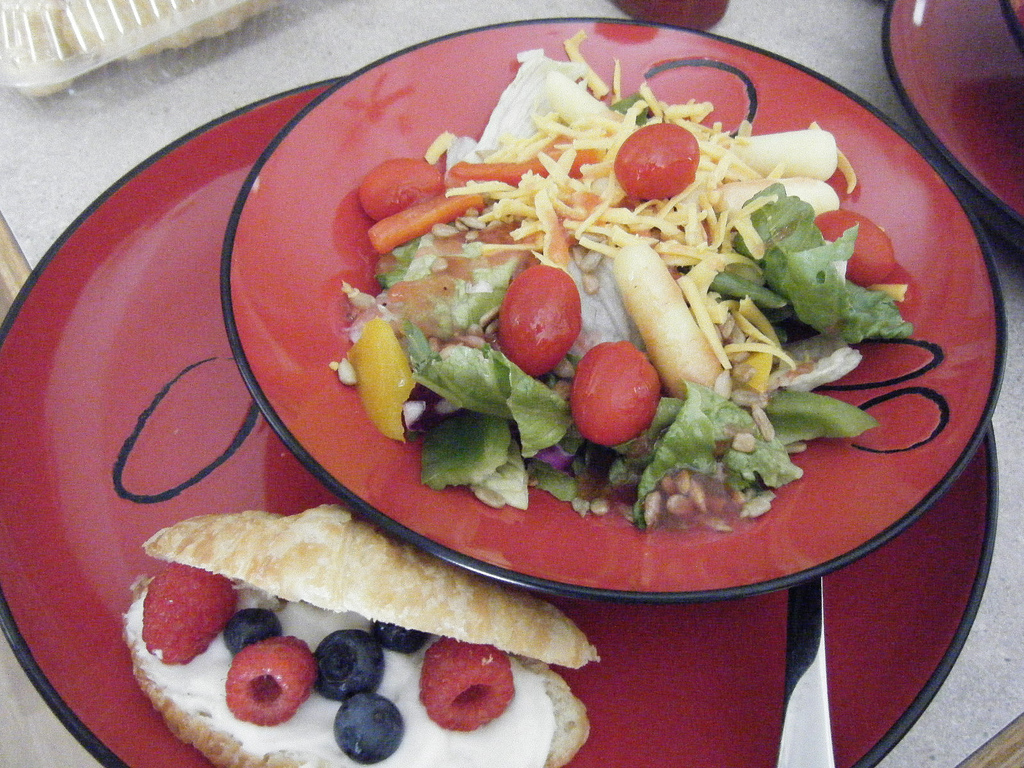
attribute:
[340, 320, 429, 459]
pepper — yellow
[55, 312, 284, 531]
design — black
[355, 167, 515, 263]
carrot — slice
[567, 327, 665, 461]
olive — red, on top 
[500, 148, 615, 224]
cheese — Shredded , on top 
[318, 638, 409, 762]
olives — on top , purple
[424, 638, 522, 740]
raspberries — red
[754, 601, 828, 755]
utensil — silver, on top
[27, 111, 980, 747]
plate — red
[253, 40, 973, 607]
bowl — sitting on top 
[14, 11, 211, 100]
container — sitting on top 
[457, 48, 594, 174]
lettuce — a piece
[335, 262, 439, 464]
food — cut up, on the side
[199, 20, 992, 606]
plate — red, one, black 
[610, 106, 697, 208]
tomato — cherry 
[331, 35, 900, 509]
salad — one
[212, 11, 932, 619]
plate — one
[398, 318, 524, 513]
lettuce — some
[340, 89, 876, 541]
salad — some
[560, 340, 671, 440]
tomato — one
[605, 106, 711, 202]
tomato — red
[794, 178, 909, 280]
tomato — red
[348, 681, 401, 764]
blueberry — one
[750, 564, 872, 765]
utensil — one, silver 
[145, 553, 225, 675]
raspberry — one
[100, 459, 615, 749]
bread — some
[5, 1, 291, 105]
container — one